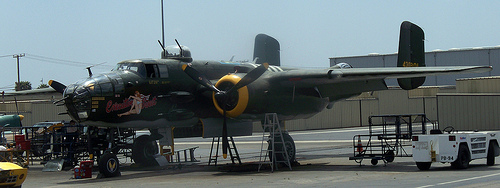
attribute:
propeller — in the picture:
[177, 60, 270, 160]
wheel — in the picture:
[265, 125, 297, 170]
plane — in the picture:
[39, 20, 491, 169]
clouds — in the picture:
[302, 21, 334, 42]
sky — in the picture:
[214, 3, 483, 40]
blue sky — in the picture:
[1, 4, 140, 45]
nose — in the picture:
[59, 59, 157, 144]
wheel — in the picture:
[448, 146, 469, 171]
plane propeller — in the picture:
[181, 49, 291, 151]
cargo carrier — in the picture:
[334, 90, 496, 185]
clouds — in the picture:
[275, 11, 360, 31]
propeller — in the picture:
[166, 55, 273, 162]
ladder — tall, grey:
[223, 134, 247, 174]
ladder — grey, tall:
[198, 132, 225, 168]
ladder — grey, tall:
[153, 145, 211, 180]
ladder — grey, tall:
[259, 105, 300, 172]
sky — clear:
[296, 12, 335, 37]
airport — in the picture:
[18, 21, 498, 185]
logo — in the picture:
[100, 84, 170, 115]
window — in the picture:
[144, 60, 174, 81]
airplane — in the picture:
[52, 35, 468, 170]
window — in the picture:
[143, 62, 167, 77]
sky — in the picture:
[176, 19, 375, 42]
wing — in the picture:
[296, 26, 488, 100]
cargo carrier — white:
[413, 120, 498, 171]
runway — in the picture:
[95, 55, 497, 182]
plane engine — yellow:
[183, 60, 275, 122]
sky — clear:
[194, 11, 279, 30]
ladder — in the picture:
[256, 111, 293, 173]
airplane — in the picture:
[48, 30, 491, 177]